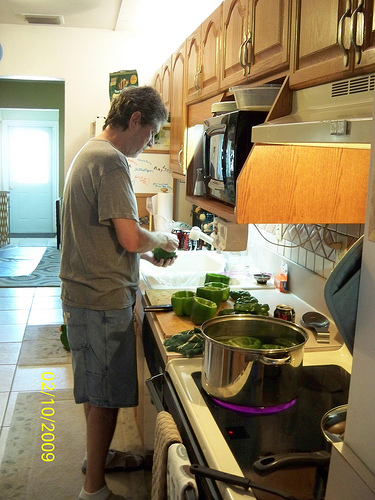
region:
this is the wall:
[299, 275, 315, 293]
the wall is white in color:
[297, 271, 311, 297]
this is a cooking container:
[203, 315, 307, 399]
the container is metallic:
[211, 367, 236, 384]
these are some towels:
[149, 414, 193, 499]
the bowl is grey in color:
[70, 165, 95, 274]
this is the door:
[17, 127, 47, 238]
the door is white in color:
[24, 203, 46, 227]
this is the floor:
[6, 370, 32, 386]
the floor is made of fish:
[8, 369, 32, 386]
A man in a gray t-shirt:
[59, 83, 173, 498]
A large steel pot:
[194, 305, 310, 419]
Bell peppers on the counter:
[169, 278, 231, 321]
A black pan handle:
[252, 443, 331, 477]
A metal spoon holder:
[300, 304, 334, 346]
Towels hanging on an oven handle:
[141, 405, 205, 497]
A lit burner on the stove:
[208, 392, 299, 422]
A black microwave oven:
[195, 107, 267, 207]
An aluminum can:
[271, 300, 297, 327]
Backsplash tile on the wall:
[270, 222, 359, 265]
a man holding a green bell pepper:
[50, 85, 182, 300]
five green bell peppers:
[160, 267, 237, 325]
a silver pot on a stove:
[184, 314, 313, 423]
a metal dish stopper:
[249, 265, 280, 287]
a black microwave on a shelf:
[205, 108, 249, 213]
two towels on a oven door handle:
[148, 379, 193, 499]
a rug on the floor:
[7, 234, 57, 311]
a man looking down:
[76, 82, 171, 231]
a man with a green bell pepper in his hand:
[36, 73, 184, 286]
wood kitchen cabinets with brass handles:
[171, 11, 303, 98]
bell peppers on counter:
[171, 270, 235, 317]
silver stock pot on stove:
[199, 315, 306, 405]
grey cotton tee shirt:
[64, 141, 140, 307]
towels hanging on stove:
[154, 412, 195, 499]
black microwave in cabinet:
[202, 113, 254, 202]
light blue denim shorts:
[60, 297, 140, 407]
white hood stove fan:
[264, 88, 374, 148]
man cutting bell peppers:
[58, 86, 175, 499]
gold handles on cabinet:
[238, 34, 251, 73]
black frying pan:
[255, 400, 346, 486]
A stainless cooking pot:
[198, 313, 307, 408]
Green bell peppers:
[170, 289, 218, 323]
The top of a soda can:
[276, 303, 295, 318]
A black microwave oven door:
[200, 112, 236, 206]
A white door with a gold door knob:
[5, 121, 56, 234]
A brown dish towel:
[150, 407, 170, 497]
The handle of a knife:
[142, 303, 170, 311]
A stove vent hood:
[250, 74, 374, 146]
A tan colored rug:
[0, 389, 147, 499]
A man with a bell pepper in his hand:
[58, 85, 178, 496]